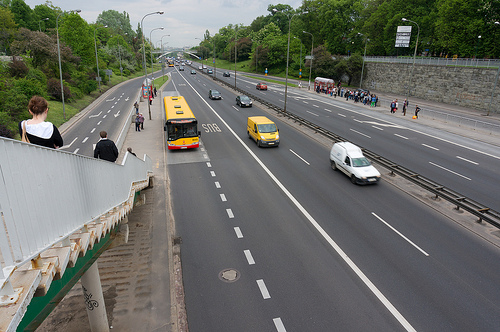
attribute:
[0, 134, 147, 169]
rail — white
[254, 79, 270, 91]
car — red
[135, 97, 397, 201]
cars — traveling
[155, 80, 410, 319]
lanes — for traffic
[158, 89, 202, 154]
bus — stopped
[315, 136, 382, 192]
car — white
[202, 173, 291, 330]
dotted line — white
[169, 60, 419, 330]
line — white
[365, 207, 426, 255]
line — white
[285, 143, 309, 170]
line — white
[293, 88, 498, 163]
line — white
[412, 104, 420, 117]
person — standing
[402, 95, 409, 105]
person — standing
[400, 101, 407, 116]
person — standing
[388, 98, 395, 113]
person — standing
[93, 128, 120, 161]
person — walking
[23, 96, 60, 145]
person — walking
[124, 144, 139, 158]
person — walking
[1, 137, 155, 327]
steps — long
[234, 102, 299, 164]
van — yellow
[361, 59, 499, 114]
wall — gray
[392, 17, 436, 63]
sign — black, white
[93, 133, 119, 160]
outerwear — black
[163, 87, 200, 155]
bus — yellow, red trimmed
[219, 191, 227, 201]
lines — white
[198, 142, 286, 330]
line — broken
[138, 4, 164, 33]
light — street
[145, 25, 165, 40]
light — street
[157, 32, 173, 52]
light — street